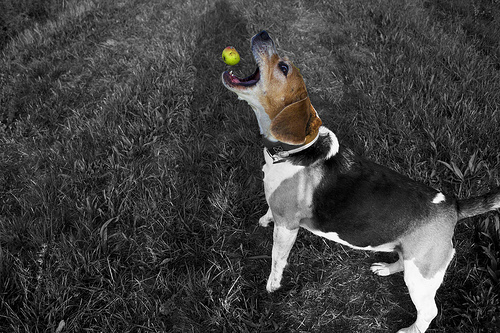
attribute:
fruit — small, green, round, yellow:
[221, 42, 244, 70]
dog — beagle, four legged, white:
[219, 29, 499, 332]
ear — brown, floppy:
[257, 97, 314, 152]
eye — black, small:
[275, 61, 293, 82]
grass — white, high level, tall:
[3, 1, 499, 332]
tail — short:
[457, 191, 498, 226]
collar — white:
[263, 133, 322, 165]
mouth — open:
[223, 41, 261, 91]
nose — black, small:
[250, 26, 278, 62]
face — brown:
[260, 58, 307, 106]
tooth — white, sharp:
[229, 67, 236, 79]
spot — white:
[430, 190, 450, 211]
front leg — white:
[263, 210, 301, 294]